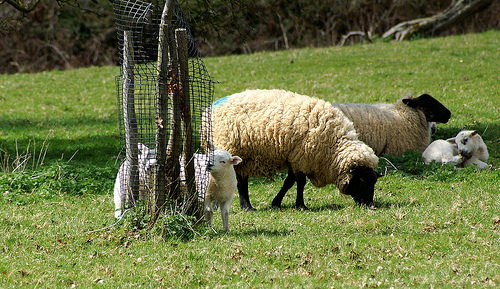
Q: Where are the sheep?
A: In the grass.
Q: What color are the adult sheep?
A: Tan.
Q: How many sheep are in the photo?
A: 5.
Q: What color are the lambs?
A: White.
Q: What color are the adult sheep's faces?
A: Black.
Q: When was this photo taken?
A: During the day.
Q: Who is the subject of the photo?
A: The sheep.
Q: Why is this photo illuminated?
A: Sunlight.